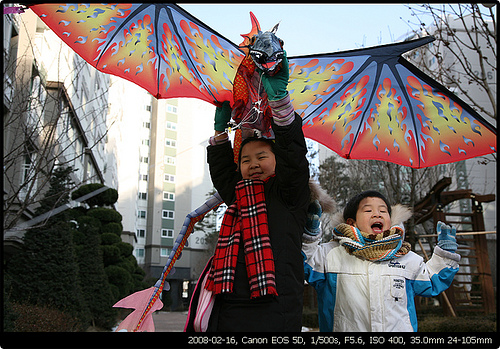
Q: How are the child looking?
A: Laughing.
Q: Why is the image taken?
A: Remembrance.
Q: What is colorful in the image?
A: Kite.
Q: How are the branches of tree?
A: Bare.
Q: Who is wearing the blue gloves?
A: The girl.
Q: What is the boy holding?
A: A kite.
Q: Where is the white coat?
A: On the girl.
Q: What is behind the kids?
A: Buildings.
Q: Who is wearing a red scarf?
A: The boy.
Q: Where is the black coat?
A: On the boy.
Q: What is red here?
A: The scarf.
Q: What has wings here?
A: The kite.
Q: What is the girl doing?
A: Laughing.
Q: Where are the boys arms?
A: Raised up.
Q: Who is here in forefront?
A: Kids.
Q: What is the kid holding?
A: Kite.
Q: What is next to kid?
A: Bushes.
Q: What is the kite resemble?
A: Dragon.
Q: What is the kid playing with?
A: Kite.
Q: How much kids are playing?
A: 2.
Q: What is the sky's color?
A: Blue.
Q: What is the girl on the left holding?
A: Dragon.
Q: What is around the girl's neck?
A: Scarf.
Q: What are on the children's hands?
A: Mittens.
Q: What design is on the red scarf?
A: Plaid.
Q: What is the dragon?
A: A kite.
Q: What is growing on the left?
A: Tree.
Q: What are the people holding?
A: Dragon kite.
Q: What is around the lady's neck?
A: Scarf.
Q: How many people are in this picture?
A: Two.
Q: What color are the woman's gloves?
A: Blue.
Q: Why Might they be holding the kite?
A: Chinese Tradition.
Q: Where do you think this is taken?
A: In China.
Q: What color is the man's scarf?
A: Red.